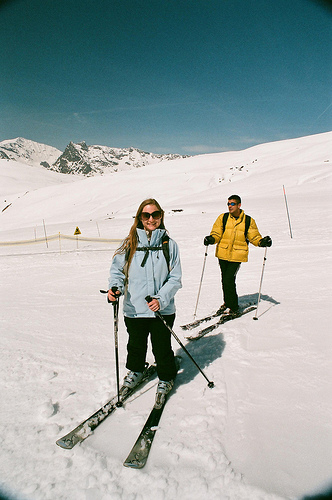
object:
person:
[107, 196, 184, 394]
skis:
[121, 354, 176, 471]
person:
[201, 192, 274, 316]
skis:
[180, 303, 260, 342]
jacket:
[106, 227, 179, 320]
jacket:
[210, 210, 264, 264]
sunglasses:
[137, 210, 164, 222]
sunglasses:
[226, 200, 241, 203]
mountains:
[1, 135, 63, 179]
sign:
[73, 225, 82, 240]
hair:
[117, 196, 164, 288]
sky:
[0, 0, 332, 156]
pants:
[215, 258, 243, 311]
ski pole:
[143, 295, 217, 388]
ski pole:
[109, 284, 120, 408]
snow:
[0, 131, 332, 500]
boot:
[119, 364, 147, 391]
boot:
[154, 373, 176, 392]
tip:
[207, 382, 215, 389]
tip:
[115, 399, 122, 409]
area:
[1, 136, 332, 500]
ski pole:
[253, 241, 269, 324]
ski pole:
[189, 242, 211, 328]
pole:
[281, 183, 295, 240]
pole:
[41, 216, 53, 263]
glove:
[202, 234, 216, 247]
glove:
[259, 235, 271, 249]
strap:
[220, 212, 230, 234]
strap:
[243, 215, 253, 241]